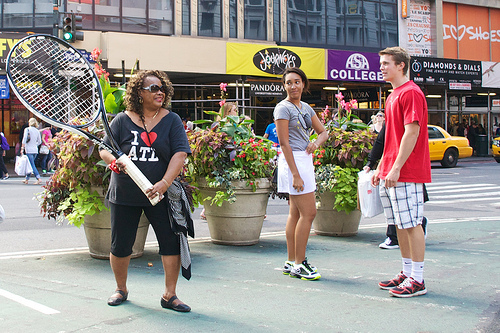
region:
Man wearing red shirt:
[370, 46, 432, 297]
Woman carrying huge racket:
[104, 70, 196, 312]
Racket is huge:
[3, 32, 164, 204]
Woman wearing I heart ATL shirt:
[97, 69, 197, 314]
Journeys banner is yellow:
[225, 39, 325, 77]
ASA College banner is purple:
[327, 48, 394, 83]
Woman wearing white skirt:
[272, 62, 327, 280]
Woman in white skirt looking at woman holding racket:
[275, 68, 327, 280]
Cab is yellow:
[425, 124, 472, 167]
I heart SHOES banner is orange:
[440, 2, 498, 61]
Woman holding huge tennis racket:
[97, 70, 189, 315]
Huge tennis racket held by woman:
[5, 30, 161, 205]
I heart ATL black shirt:
[100, 110, 180, 210]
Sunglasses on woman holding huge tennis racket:
[137, 81, 168, 94]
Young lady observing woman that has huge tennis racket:
[272, 67, 327, 282]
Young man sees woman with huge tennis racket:
[373, 44, 433, 299]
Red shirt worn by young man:
[376, 80, 433, 182]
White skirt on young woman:
[273, 151, 316, 197]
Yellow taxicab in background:
[420, 119, 474, 169]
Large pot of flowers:
[189, 80, 276, 245]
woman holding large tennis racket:
[1, 17, 252, 308]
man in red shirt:
[362, 58, 457, 298]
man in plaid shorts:
[350, 51, 450, 319]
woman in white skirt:
[250, 54, 344, 324]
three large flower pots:
[40, 127, 461, 289]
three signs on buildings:
[197, 21, 497, 108]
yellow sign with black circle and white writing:
[222, 27, 340, 104]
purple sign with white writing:
[331, 37, 429, 99]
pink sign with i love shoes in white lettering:
[434, 14, 498, 74]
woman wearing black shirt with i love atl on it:
[112, 74, 207, 286]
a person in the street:
[266, 58, 325, 285]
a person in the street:
[373, 45, 438, 300]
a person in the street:
[362, 116, 432, 250]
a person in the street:
[78, 54, 198, 312]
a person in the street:
[369, 107, 389, 137]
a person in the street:
[216, 100, 243, 130]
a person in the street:
[265, 113, 284, 145]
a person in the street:
[18, 108, 46, 186]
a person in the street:
[33, 120, 56, 168]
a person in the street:
[0, 125, 16, 181]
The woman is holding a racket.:
[7, 25, 177, 210]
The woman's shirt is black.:
[110, 111, 195, 206]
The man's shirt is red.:
[372, 77, 442, 174]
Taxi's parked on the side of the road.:
[347, 96, 499, 162]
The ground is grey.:
[203, 257, 352, 332]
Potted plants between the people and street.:
[189, 48, 272, 253]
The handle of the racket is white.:
[85, 116, 175, 224]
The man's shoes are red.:
[361, 244, 434, 304]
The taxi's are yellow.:
[412, 105, 499, 163]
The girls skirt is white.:
[260, 125, 330, 204]